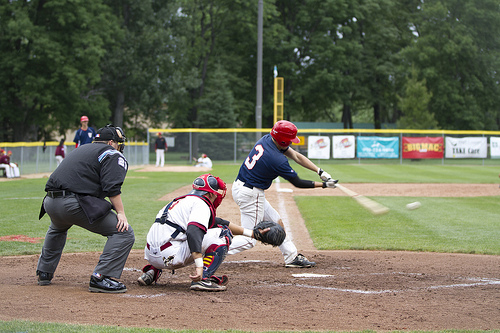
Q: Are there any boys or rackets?
A: No, there are no boys or rackets.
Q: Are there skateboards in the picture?
A: No, there are no skateboards.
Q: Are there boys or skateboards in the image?
A: No, there are no skateboards or boys.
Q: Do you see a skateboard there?
A: No, there are no skateboards.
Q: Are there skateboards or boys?
A: No, there are no skateboards or boys.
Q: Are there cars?
A: No, there are no cars.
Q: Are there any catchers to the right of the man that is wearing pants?
A: Yes, there is a catcher to the right of the man.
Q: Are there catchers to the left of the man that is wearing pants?
A: No, the catcher is to the right of the man.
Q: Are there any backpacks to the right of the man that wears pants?
A: No, there is a catcher to the right of the man.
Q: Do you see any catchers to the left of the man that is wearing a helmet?
A: Yes, there is a catcher to the left of the man.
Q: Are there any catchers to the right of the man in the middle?
A: No, the catcher is to the left of the man.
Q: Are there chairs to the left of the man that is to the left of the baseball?
A: No, there is a catcher to the left of the man.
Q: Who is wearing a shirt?
A: The catcher is wearing a shirt.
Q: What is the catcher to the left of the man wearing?
A: The catcher is wearing a shirt.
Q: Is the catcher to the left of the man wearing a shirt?
A: Yes, the catcher is wearing a shirt.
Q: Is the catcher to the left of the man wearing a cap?
A: No, the catcher is wearing a shirt.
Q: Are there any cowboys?
A: No, there are no cowboys.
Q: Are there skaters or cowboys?
A: No, there are no cowboys or skaters.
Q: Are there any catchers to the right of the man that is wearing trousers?
A: Yes, there is a catcher to the right of the man.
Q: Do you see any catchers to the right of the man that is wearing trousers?
A: Yes, there is a catcher to the right of the man.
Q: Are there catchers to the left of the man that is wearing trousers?
A: No, the catcher is to the right of the man.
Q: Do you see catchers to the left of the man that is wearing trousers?
A: No, the catcher is to the right of the man.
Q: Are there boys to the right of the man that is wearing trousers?
A: No, there is a catcher to the right of the man.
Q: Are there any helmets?
A: Yes, there is a helmet.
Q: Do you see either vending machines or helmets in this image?
A: Yes, there is a helmet.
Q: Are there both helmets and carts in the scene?
A: No, there is a helmet but no carts.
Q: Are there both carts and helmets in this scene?
A: No, there is a helmet but no carts.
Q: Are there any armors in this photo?
A: No, there are no armors.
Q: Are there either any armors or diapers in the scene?
A: No, there are no armors or diapers.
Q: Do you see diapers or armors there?
A: No, there are no armors or diapers.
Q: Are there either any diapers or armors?
A: No, there are no armors or diapers.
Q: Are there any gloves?
A: Yes, there are gloves.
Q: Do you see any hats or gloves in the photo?
A: Yes, there are gloves.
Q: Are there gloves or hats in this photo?
A: Yes, there are gloves.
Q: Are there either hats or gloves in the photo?
A: Yes, there are gloves.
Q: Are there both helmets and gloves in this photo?
A: Yes, there are both gloves and a helmet.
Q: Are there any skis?
A: No, there are no skis.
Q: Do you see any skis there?
A: No, there are no skis.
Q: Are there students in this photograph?
A: No, there are no students.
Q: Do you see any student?
A: No, there are no students.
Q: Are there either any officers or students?
A: No, there are no students or officers.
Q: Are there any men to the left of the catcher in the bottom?
A: Yes, there is a man to the left of the catcher.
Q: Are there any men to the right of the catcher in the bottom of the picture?
A: No, the man is to the left of the catcher.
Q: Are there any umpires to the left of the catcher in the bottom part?
A: No, there is a man to the left of the catcher.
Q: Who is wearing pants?
A: The man is wearing pants.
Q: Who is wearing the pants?
A: The man is wearing pants.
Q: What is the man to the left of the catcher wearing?
A: The man is wearing trousers.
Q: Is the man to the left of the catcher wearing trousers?
A: Yes, the man is wearing trousers.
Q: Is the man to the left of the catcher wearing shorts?
A: No, the man is wearing trousers.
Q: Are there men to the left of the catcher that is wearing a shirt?
A: Yes, there is a man to the left of the catcher.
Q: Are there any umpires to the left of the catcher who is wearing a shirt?
A: No, there is a man to the left of the catcher.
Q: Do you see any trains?
A: No, there are no trains.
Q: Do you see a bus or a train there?
A: No, there are no trains or buses.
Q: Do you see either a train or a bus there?
A: No, there are no trains or buses.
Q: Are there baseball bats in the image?
A: Yes, there is a baseball bat.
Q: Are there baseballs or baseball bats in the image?
A: Yes, there is a baseball bat.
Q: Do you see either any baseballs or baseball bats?
A: Yes, there is a baseball bat.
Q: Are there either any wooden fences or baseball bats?
A: Yes, there is a wood baseball bat.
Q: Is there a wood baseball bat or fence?
A: Yes, there is a wood baseball bat.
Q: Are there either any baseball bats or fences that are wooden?
A: Yes, the baseball bat is wooden.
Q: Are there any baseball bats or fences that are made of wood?
A: Yes, the baseball bat is made of wood.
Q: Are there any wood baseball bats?
A: Yes, there is a wood baseball bat.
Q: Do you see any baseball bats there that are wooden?
A: Yes, there is a baseball bat that is wooden.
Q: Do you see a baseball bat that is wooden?
A: Yes, there is a baseball bat that is wooden.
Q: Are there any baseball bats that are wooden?
A: Yes, there is a baseball bat that is wooden.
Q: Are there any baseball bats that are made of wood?
A: Yes, there is a baseball bat that is made of wood.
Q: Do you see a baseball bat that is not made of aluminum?
A: Yes, there is a baseball bat that is made of wood.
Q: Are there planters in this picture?
A: No, there are no planters.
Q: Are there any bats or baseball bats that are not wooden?
A: No, there is a baseball bat but it is wooden.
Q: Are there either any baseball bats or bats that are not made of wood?
A: No, there is a baseball bat but it is made of wood.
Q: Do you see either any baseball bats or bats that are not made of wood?
A: No, there is a baseball bat but it is made of wood.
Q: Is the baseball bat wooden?
A: Yes, the baseball bat is wooden.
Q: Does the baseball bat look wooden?
A: Yes, the baseball bat is wooden.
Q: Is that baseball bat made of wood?
A: Yes, the baseball bat is made of wood.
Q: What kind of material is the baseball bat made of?
A: The baseball bat is made of wood.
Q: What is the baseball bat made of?
A: The baseball bat is made of wood.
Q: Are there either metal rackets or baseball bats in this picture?
A: No, there is a baseball bat but it is wooden.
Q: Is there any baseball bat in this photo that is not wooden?
A: No, there is a baseball bat but it is wooden.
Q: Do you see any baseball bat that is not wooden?
A: No, there is a baseball bat but it is wooden.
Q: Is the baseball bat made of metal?
A: No, the baseball bat is made of wood.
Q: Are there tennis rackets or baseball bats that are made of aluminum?
A: No, there is a baseball bat but it is made of wood.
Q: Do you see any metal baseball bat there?
A: No, there is a baseball bat but it is made of wood.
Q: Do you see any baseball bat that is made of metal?
A: No, there is a baseball bat but it is made of wood.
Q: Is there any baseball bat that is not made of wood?
A: No, there is a baseball bat but it is made of wood.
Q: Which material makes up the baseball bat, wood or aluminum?
A: The baseball bat is made of wood.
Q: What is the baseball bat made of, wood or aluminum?
A: The baseball bat is made of wood.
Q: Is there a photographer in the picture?
A: No, there are no photographers.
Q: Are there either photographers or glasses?
A: No, there are no photographers or glasses.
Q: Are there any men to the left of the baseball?
A: Yes, there is a man to the left of the baseball.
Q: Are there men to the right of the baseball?
A: No, the man is to the left of the baseball.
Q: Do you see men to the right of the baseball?
A: No, the man is to the left of the baseball.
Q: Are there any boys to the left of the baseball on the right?
A: No, there is a man to the left of the baseball.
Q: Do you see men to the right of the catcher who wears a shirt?
A: Yes, there is a man to the right of the catcher.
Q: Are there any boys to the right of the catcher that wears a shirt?
A: No, there is a man to the right of the catcher.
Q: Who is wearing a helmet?
A: The man is wearing a helmet.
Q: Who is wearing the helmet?
A: The man is wearing a helmet.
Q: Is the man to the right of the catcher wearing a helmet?
A: Yes, the man is wearing a helmet.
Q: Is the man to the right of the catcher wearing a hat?
A: No, the man is wearing a helmet.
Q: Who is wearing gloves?
A: The man is wearing gloves.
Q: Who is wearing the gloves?
A: The man is wearing gloves.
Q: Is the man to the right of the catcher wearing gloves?
A: Yes, the man is wearing gloves.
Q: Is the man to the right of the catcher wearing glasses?
A: No, the man is wearing gloves.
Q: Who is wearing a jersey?
A: The man is wearing a jersey.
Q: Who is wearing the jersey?
A: The man is wearing a jersey.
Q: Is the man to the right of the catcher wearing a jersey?
A: Yes, the man is wearing a jersey.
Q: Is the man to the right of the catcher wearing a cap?
A: No, the man is wearing a jersey.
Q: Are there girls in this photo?
A: No, there are no girls.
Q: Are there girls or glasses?
A: No, there are no girls or glasses.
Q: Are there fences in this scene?
A: Yes, there is a fence.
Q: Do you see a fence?
A: Yes, there is a fence.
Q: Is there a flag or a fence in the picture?
A: Yes, there is a fence.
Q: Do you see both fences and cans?
A: No, there is a fence but no cans.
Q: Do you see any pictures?
A: No, there are no pictures.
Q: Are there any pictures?
A: No, there are no pictures.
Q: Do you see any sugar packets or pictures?
A: No, there are no pictures or sugar packets.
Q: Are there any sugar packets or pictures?
A: No, there are no pictures or sugar packets.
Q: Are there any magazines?
A: No, there are no magazines.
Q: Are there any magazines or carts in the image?
A: No, there are no magazines or carts.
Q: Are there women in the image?
A: No, there are no women.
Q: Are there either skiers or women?
A: No, there are no women or skiers.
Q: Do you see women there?
A: No, there are no women.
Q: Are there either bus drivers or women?
A: No, there are no women or bus drivers.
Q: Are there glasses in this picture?
A: No, there are no glasses.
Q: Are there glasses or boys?
A: No, there are no glasses or boys.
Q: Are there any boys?
A: No, there are no boys.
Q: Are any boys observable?
A: No, there are no boys.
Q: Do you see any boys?
A: No, there are no boys.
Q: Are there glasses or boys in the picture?
A: No, there are no boys or glasses.